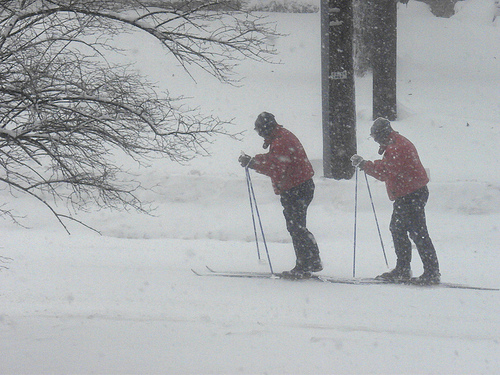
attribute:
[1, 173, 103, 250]
branch — leafless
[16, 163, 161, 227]
branch — leafless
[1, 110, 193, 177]
branch — leafless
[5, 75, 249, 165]
branch — leafless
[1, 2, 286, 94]
branch — leafless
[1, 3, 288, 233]
branches — snow covered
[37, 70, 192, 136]
branch — arch shape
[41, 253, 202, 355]
snow — heavy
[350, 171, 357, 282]
poles — skinny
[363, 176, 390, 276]
poles — skinny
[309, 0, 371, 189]
pole — vertical, metal, utility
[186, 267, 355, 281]
ski — snow covered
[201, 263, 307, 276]
ski — snow covered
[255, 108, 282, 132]
hat — grey, wholly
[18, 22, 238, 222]
trees — bare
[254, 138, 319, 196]
jacket — red